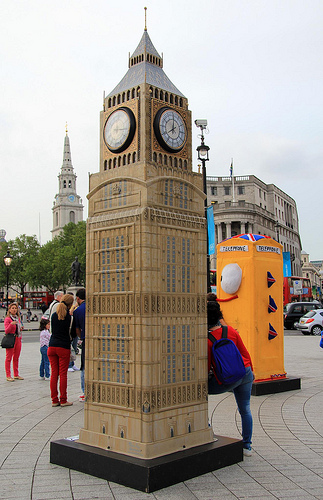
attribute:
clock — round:
[148, 100, 193, 153]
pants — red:
[39, 347, 75, 409]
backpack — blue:
[213, 339, 245, 390]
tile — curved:
[12, 423, 55, 499]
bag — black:
[1, 324, 19, 360]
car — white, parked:
[300, 302, 322, 339]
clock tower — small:
[108, 39, 260, 465]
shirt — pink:
[33, 330, 58, 354]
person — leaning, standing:
[204, 304, 260, 429]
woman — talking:
[56, 298, 83, 405]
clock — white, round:
[103, 111, 139, 153]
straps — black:
[205, 332, 230, 347]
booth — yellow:
[239, 247, 282, 381]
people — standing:
[10, 280, 83, 394]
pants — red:
[2, 356, 23, 386]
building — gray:
[49, 156, 93, 233]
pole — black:
[200, 164, 217, 280]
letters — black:
[224, 246, 251, 256]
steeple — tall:
[58, 120, 85, 173]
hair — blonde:
[60, 296, 69, 317]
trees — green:
[41, 233, 64, 278]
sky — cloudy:
[231, 84, 301, 194]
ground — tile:
[266, 405, 306, 493]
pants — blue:
[81, 361, 90, 396]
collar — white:
[211, 325, 225, 332]